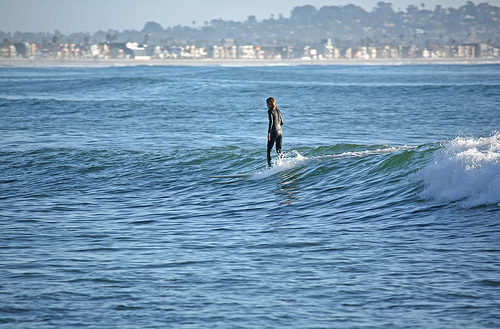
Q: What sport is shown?
A: Surfing.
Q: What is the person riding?
A: Surfboard.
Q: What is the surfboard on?
A: Wave.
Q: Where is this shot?
A: Beach.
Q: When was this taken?
A: Daytime.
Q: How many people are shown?
A: 1.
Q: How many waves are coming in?
A: 2.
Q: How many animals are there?
A: 0.